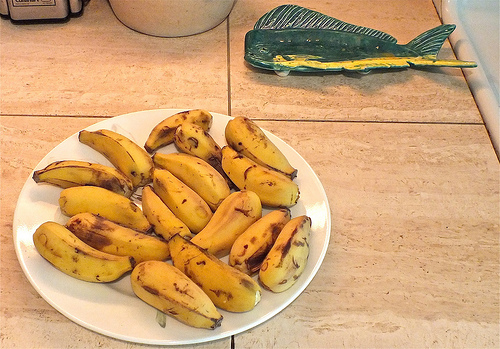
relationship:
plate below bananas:
[12, 108, 332, 346] [32, 111, 316, 329]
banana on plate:
[31, 109, 312, 330] [8, 100, 335, 347]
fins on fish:
[249, 2, 401, 47] [237, 2, 482, 87]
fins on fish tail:
[406, 23, 455, 53] [406, 24, 477, 68]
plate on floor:
[8, 100, 335, 347] [1, 0, 498, 347]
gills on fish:
[269, 21, 350, 49] [237, 2, 482, 87]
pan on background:
[107, 0, 234, 36] [4, 9, 474, 36]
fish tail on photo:
[406, 21, 461, 68] [8, 11, 498, 347]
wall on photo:
[461, 3, 499, 67] [8, 11, 498, 347]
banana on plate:
[31, 109, 312, 330] [27, 283, 114, 343]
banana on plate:
[31, 109, 312, 330] [94, 89, 156, 121]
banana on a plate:
[31, 109, 312, 330] [8, 100, 335, 347]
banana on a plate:
[219, 142, 300, 209] [8, 100, 335, 347]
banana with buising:
[31, 109, 312, 330] [86, 219, 104, 258]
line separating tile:
[252, 114, 484, 127] [339, 127, 472, 319]